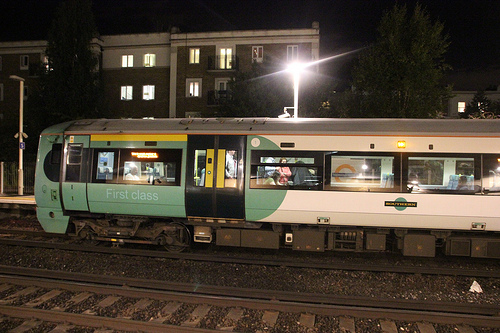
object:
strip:
[91, 135, 188, 142]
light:
[252, 52, 346, 114]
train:
[33, 112, 498, 260]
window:
[402, 155, 499, 195]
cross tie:
[379, 317, 400, 333]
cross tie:
[415, 321, 438, 333]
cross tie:
[337, 317, 355, 332]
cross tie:
[300, 312, 314, 330]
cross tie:
[255, 309, 278, 333]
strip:
[203, 147, 225, 189]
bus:
[33, 117, 499, 258]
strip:
[9, 234, 28, 241]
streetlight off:
[8, 75, 27, 197]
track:
[0, 264, 500, 333]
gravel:
[3, 204, 498, 329]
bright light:
[250, 42, 370, 102]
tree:
[28, 19, 109, 122]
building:
[0, 23, 363, 137]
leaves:
[357, 0, 451, 62]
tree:
[347, 1, 458, 123]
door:
[185, 133, 247, 219]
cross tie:
[178, 302, 213, 328]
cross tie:
[115, 295, 154, 320]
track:
[0, 228, 500, 280]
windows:
[92, 147, 179, 185]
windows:
[188, 81, 201, 98]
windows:
[250, 153, 322, 189]